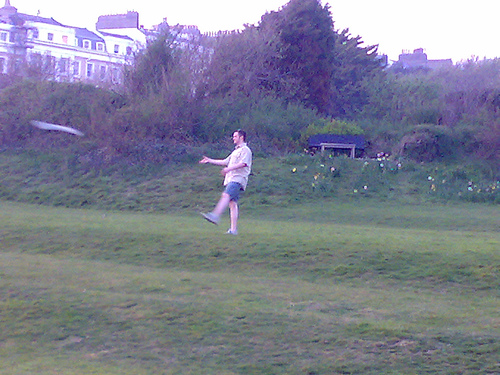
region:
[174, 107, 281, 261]
this is a person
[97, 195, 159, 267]
this is grass on the field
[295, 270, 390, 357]
this is grass on the field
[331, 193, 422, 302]
this is grass on the field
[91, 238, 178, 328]
this is grass on the field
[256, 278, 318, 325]
this is grass on the field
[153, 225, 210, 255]
this is grass on the field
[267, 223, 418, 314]
this is grass on the field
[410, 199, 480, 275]
this is grass on the field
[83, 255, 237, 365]
this is grass on the field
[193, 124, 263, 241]
Man standing in a grass field on one leg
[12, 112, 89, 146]
Dark colored object flying through the air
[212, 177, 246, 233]
Short dark blue shorts being worn by a person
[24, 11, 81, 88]
Tall white colored building with multiple windows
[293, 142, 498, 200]
Field of dark grass and colorful flowers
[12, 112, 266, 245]
Man who just threw an object following through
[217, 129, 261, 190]
Man wearing a light white colored shirt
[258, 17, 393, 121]
Tall thick stand of trees in fall coloring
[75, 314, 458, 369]
Short dark green grass with patchy dirt visible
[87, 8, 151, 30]
Dark red brick roof of a building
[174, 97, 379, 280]
a man on a field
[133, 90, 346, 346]
a man on the grass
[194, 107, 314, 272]
a man on the green grass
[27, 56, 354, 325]
a man playing freesbee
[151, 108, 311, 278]
a man eraing a shirt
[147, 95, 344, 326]
a man wearing shorts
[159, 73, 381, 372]
a man wearing shoes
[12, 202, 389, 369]
a field of grass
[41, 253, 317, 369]
a field of green grass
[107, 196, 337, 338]
a green grass field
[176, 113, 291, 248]
the man is standing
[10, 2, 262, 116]
buildings in the distance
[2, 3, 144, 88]
buildings in the distance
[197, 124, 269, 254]
man in the grass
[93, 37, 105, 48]
window on the house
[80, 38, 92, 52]
window on the house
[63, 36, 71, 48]
window on the house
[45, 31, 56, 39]
window on the house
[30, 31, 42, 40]
window on the house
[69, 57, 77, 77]
window on the house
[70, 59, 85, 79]
window on the house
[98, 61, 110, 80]
window on the house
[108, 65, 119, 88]
window on the house